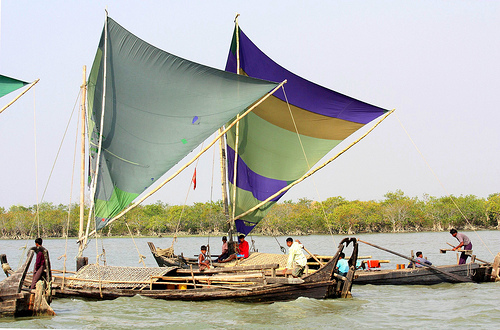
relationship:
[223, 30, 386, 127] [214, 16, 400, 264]
trim on sail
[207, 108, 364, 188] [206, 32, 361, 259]
green stripe on sail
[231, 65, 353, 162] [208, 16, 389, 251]
brown stripe on sail